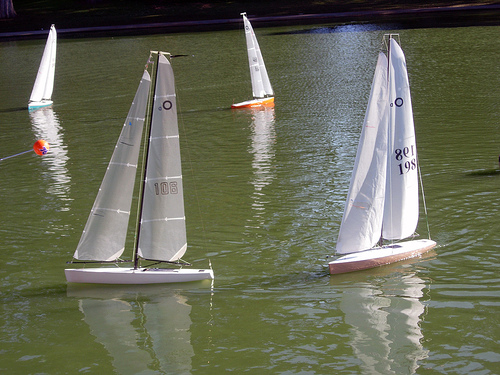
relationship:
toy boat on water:
[65, 50, 214, 284] [0, 6, 499, 374]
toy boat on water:
[328, 33, 436, 276] [0, 6, 499, 374]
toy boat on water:
[29, 23, 57, 113] [0, 6, 499, 374]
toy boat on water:
[232, 12, 276, 113] [0, 6, 499, 374]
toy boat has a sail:
[65, 50, 214, 284] [74, 52, 188, 261]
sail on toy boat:
[241, 12, 274, 98] [232, 12, 276, 113]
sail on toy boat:
[29, 24, 57, 103] [29, 23, 57, 113]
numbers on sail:
[153, 181, 178, 195] [74, 52, 188, 261]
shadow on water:
[462, 155, 499, 177] [0, 6, 499, 374]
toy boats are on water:
[28, 12, 436, 283] [0, 6, 499, 374]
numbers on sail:
[395, 146, 416, 174] [335, 38, 419, 255]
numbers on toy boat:
[395, 146, 416, 174] [328, 33, 436, 276]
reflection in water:
[29, 104, 432, 374] [0, 6, 499, 374]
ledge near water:
[1, 0, 499, 43] [0, 6, 499, 374]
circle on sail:
[162, 99, 172, 110] [74, 52, 188, 261]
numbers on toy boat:
[153, 181, 178, 195] [65, 50, 214, 284]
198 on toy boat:
[398, 158, 416, 175] [328, 33, 436, 276]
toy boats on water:
[28, 12, 436, 283] [0, 6, 499, 374]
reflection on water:
[29, 104, 432, 374] [0, 6, 499, 374]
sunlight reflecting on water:
[1, 20, 500, 374] [0, 6, 499, 374]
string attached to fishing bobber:
[1, 149, 33, 160] [33, 139, 50, 155]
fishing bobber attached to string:
[33, 139, 50, 155] [1, 149, 33, 160]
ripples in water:
[1, 24, 498, 375] [0, 6, 499, 374]